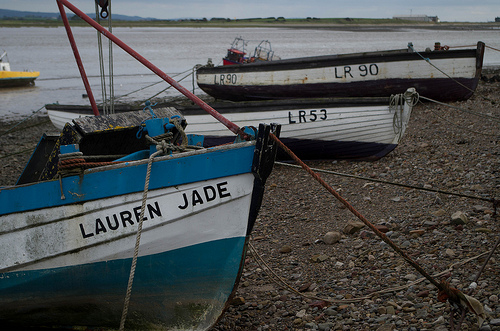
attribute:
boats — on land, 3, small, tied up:
[108, 44, 415, 222]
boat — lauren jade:
[15, 158, 254, 312]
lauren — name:
[71, 202, 185, 258]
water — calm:
[138, 29, 203, 51]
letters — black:
[217, 175, 233, 203]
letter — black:
[279, 106, 297, 132]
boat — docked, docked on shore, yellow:
[3, 47, 32, 95]